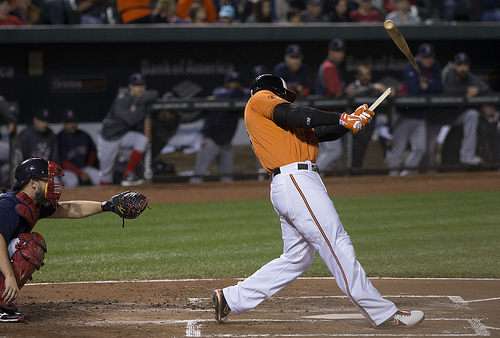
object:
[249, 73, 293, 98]
hat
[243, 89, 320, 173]
shirt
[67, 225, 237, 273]
grass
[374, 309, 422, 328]
shoes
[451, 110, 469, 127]
ground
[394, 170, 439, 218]
ground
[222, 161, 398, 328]
pants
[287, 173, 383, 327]
orange stripe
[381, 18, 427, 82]
bat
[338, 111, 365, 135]
gloves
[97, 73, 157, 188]
guy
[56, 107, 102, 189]
guy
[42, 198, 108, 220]
left arm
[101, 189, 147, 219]
mitt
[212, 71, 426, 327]
batter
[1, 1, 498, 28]
people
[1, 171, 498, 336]
field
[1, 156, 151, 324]
catcher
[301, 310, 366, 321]
home plate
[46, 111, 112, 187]
players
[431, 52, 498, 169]
player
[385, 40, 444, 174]
player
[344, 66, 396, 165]
player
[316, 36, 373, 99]
player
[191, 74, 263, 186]
player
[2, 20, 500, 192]
dugout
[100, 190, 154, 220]
mit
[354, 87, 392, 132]
bat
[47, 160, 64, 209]
face mask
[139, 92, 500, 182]
fence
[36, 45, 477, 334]
game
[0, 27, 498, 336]
baseball